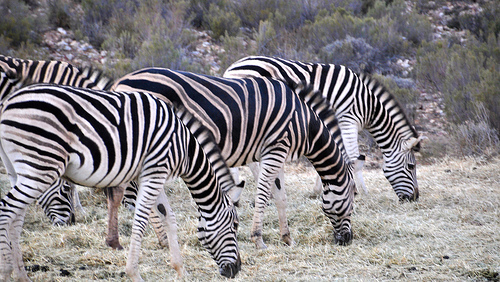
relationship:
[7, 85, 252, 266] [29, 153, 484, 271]
zebra grazing in grass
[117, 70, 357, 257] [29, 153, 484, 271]
zebra grazing in grass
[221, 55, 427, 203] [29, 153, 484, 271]
zebra grazing in grass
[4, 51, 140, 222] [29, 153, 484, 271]
zebra grazing in grass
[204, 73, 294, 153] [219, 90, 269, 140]
pattern on fur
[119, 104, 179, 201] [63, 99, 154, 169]
stripes on fur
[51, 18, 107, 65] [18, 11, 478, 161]
rocks on hill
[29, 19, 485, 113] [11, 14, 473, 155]
bushes on hill top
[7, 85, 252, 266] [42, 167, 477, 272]
zebra eating grass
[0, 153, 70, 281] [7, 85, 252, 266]
leg of a zebra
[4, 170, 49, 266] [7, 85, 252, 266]
leg of a zebra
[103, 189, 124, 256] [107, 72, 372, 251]
leg of a zebra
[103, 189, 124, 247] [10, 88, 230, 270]
leg of a zebra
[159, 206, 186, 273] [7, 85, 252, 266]
leg of a zebra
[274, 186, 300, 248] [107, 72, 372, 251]
leg of a zebra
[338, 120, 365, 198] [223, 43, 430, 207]
leg of a zebra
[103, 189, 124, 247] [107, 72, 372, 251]
leg of a zebra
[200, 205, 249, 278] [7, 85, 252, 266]
head of a zebra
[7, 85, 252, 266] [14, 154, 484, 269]
zebra grazing on ground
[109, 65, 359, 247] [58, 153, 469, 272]
zebra grazing on ground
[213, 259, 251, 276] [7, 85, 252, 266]
nose of zebra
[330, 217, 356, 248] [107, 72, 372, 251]
nose of zebra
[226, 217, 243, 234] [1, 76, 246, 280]
eye of zebra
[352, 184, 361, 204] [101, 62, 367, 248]
eye of zebra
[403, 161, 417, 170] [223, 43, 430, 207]
eye of zebra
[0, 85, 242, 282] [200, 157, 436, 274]
zebra are grazing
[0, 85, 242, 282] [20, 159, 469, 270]
zebra are in a field